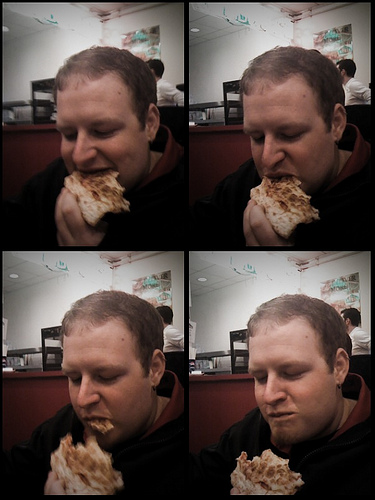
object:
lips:
[267, 409, 296, 421]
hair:
[60, 290, 164, 378]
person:
[338, 59, 372, 106]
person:
[156, 305, 184, 352]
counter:
[1, 124, 373, 252]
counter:
[2, 362, 373, 498]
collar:
[144, 370, 185, 437]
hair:
[53, 44, 159, 132]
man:
[340, 307, 372, 356]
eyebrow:
[60, 363, 80, 375]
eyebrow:
[92, 362, 125, 373]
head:
[239, 44, 347, 192]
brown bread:
[249, 175, 320, 237]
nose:
[261, 131, 285, 169]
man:
[145, 58, 184, 106]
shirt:
[157, 78, 185, 106]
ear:
[333, 347, 349, 386]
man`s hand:
[55, 187, 106, 248]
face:
[56, 76, 149, 187]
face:
[243, 90, 335, 190]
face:
[61, 327, 151, 448]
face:
[249, 322, 337, 443]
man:
[198, 293, 374, 496]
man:
[8, 45, 182, 247]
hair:
[239, 45, 345, 132]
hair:
[247, 294, 353, 375]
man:
[195, 45, 372, 247]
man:
[1, 290, 183, 496]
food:
[63, 169, 130, 225]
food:
[249, 176, 319, 238]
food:
[42, 418, 122, 495]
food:
[230, 447, 304, 495]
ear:
[149, 349, 166, 387]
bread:
[229, 447, 306, 495]